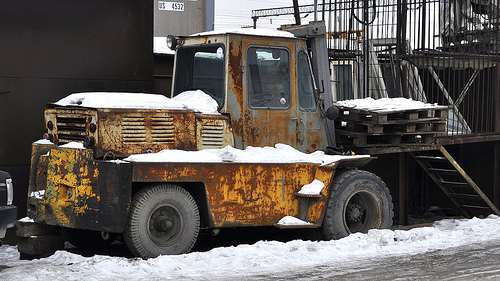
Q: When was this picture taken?
A: During the day.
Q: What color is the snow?
A: White.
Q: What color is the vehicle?
A: Yellow.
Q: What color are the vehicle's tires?
A: Black.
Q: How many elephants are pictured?
A: Zero.